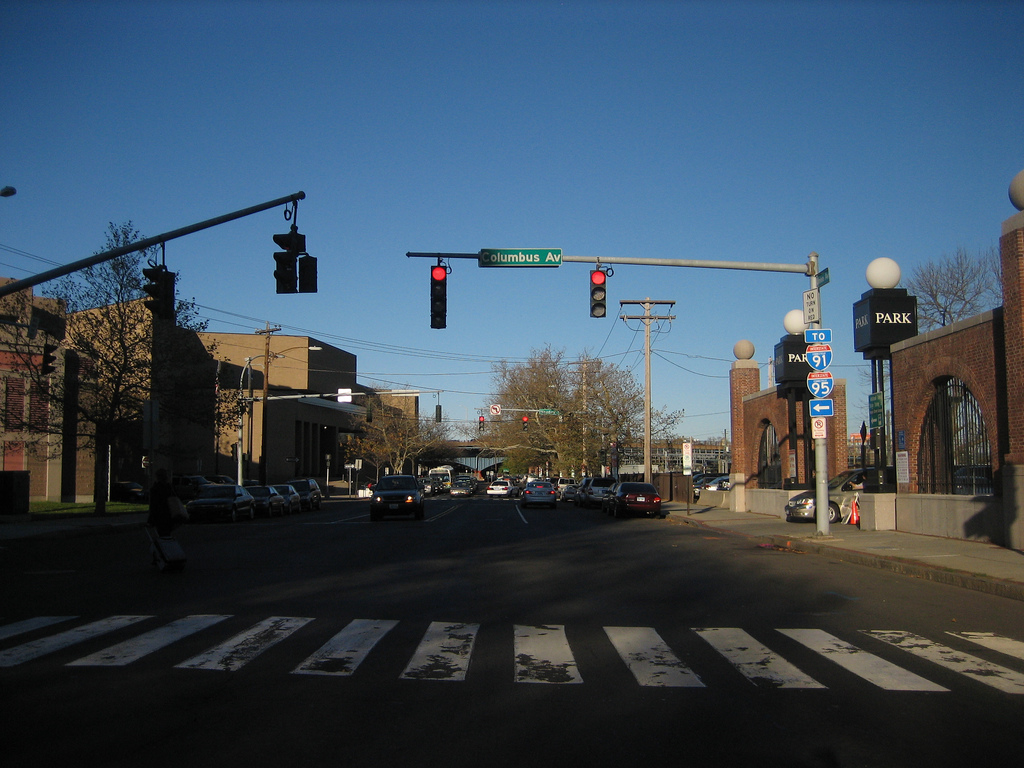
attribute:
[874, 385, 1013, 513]
glass — clear, clean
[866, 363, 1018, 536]
glass — clean, clear